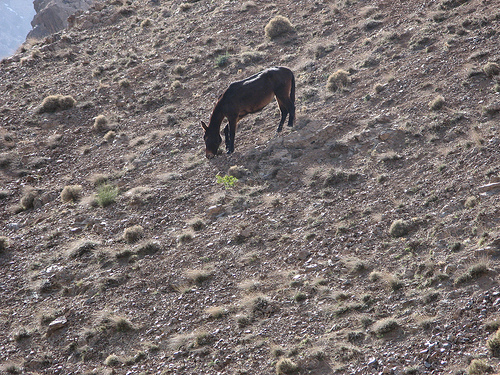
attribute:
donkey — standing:
[199, 65, 298, 156]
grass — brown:
[238, 292, 261, 316]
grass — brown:
[368, 315, 401, 335]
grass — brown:
[275, 357, 301, 372]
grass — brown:
[267, 320, 392, 365]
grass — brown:
[458, 311, 497, 357]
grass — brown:
[432, 248, 489, 291]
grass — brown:
[364, 197, 443, 237]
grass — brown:
[55, 300, 185, 368]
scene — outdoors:
[12, 47, 475, 373]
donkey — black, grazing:
[192, 65, 344, 166]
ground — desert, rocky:
[298, 275, 478, 373]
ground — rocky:
[60, 276, 311, 368]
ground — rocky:
[377, 85, 497, 267]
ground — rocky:
[146, 174, 352, 231]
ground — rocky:
[7, 60, 130, 214]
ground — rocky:
[31, 21, 200, 124]